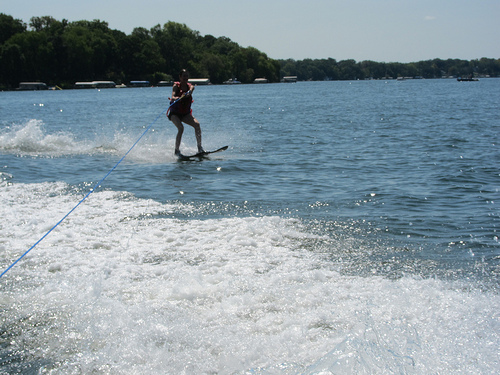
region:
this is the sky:
[280, 2, 350, 33]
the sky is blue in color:
[270, 3, 305, 22]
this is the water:
[292, 85, 390, 171]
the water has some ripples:
[382, 200, 458, 240]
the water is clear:
[322, 87, 397, 149]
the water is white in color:
[81, 272, 219, 338]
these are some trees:
[10, 17, 231, 59]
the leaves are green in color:
[156, 36, 214, 56]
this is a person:
[170, 68, 207, 145]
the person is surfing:
[160, 70, 235, 175]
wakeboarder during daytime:
[125, 64, 245, 171]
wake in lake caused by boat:
[6, 168, 480, 370]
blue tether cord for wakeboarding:
[3, 54, 234, 288]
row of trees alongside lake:
[65, 0, 496, 101]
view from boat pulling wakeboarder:
[0, 65, 458, 247]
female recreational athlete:
[128, 47, 255, 209]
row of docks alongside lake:
[0, 34, 312, 96]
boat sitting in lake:
[436, 41, 494, 95]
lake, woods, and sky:
[269, 14, 491, 117]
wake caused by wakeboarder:
[0, 57, 235, 179]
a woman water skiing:
[119, 33, 301, 237]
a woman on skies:
[97, 36, 282, 188]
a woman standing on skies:
[134, 40, 291, 192]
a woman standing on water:
[151, 46, 280, 213]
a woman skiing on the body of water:
[148, 36, 342, 237]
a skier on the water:
[109, 44, 314, 221]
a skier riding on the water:
[105, 18, 430, 293]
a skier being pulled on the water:
[72, 41, 419, 324]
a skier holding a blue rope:
[62, 57, 317, 269]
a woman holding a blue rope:
[14, 39, 352, 366]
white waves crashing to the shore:
[99, 251, 173, 290]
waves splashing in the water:
[18, 122, 117, 158]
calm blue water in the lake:
[300, 101, 451, 163]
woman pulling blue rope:
[125, 92, 201, 142]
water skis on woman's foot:
[171, 143, 233, 165]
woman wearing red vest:
[158, 79, 211, 107]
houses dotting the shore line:
[223, 68, 309, 88]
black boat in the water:
[447, 71, 486, 91]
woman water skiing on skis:
[123, 58, 249, 186]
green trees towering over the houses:
[19, 8, 121, 63]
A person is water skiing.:
[131, 72, 239, 169]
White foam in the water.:
[101, 217, 334, 349]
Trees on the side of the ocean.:
[47, 14, 413, 78]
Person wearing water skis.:
[159, 145, 249, 165]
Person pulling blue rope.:
[48, 77, 185, 232]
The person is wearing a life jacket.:
[166, 82, 206, 119]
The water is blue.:
[282, 87, 459, 185]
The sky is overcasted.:
[240, 13, 427, 52]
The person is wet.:
[147, 70, 241, 165]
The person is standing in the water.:
[121, 70, 241, 197]